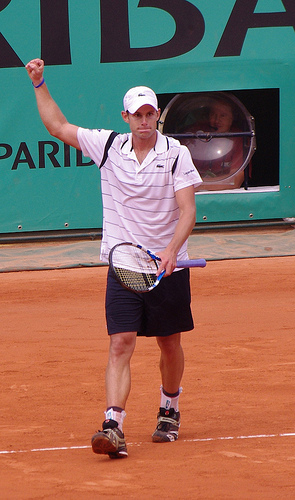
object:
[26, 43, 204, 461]
man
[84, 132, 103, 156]
white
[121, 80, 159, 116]
hat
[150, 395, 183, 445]
shoe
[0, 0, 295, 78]
wall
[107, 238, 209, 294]
racket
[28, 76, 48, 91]
bracelet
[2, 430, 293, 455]
line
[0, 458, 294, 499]
dirt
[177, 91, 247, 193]
person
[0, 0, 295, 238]
background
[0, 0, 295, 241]
cover